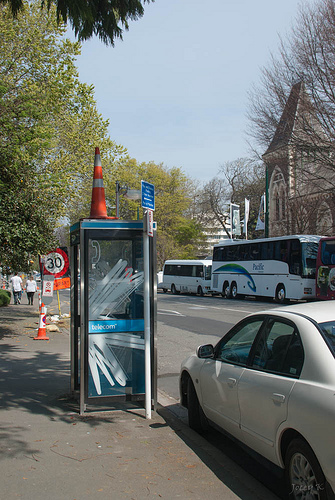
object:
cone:
[88, 143, 110, 219]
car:
[178, 298, 335, 500]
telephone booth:
[65, 217, 164, 418]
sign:
[140, 180, 156, 212]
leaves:
[24, 343, 29, 347]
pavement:
[0, 300, 274, 500]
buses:
[209, 233, 330, 298]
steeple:
[262, 72, 335, 154]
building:
[260, 75, 335, 241]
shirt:
[11, 276, 23, 292]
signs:
[41, 276, 55, 297]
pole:
[56, 290, 62, 319]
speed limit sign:
[40, 248, 68, 279]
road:
[46, 288, 335, 500]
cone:
[31, 301, 51, 341]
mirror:
[198, 344, 214, 358]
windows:
[274, 195, 279, 222]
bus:
[159, 257, 212, 296]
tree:
[0, 0, 159, 47]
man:
[9, 269, 24, 305]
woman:
[23, 272, 38, 305]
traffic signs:
[53, 277, 71, 292]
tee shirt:
[24, 279, 38, 294]